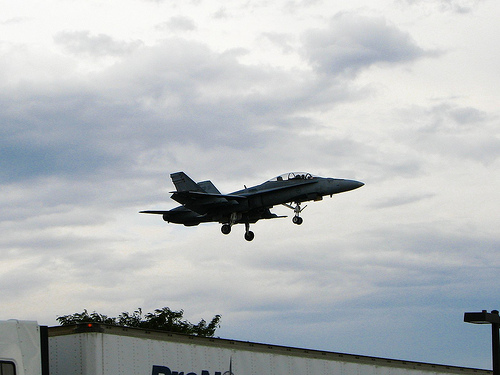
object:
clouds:
[0, 0, 500, 375]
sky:
[2, 0, 373, 88]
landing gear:
[282, 199, 307, 225]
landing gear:
[244, 216, 254, 241]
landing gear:
[221, 213, 238, 234]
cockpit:
[268, 171, 313, 182]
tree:
[54, 305, 222, 337]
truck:
[0, 318, 490, 375]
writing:
[152, 365, 234, 375]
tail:
[138, 171, 221, 226]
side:
[98, 323, 493, 374]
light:
[464, 309, 500, 324]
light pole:
[491, 309, 500, 374]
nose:
[315, 177, 365, 200]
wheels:
[292, 217, 302, 225]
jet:
[139, 170, 365, 241]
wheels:
[221, 225, 231, 235]